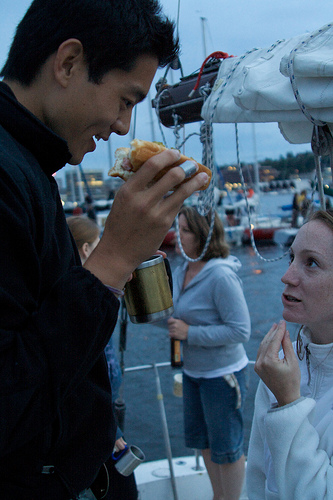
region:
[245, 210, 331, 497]
young girl looking up at young man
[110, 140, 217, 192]
sandwich in young man's right hand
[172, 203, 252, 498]
young lady standing next to the railing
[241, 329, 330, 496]
white jacket young woman is wearing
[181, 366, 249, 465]
blue jean shorts the young woman is wearing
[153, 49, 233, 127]
black and red rooster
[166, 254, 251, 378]
blue jacket woman is wearing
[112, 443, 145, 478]
blue cup person is holding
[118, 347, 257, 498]
white railing next to the young lady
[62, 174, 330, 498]
blue water boats are in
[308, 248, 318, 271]
A woman's right eye.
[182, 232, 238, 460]
A woman in the background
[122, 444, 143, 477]
A silver cup in the background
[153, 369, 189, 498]
A silver pole in the background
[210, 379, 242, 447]
Blue jeans on a woman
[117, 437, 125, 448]
A woman's hand on a cup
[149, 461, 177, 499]
Edge of a white boat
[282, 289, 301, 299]
A woman's lips partially open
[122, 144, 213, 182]
A sandwich being held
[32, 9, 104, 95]
A man's left ear.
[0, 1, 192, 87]
man with black hair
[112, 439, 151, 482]
silver and blue mug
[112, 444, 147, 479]
blue handled mug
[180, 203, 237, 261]
woman with brown hair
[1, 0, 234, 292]
man eating a hotdog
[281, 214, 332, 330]
woman with freckles on face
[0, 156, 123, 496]
man wearing black fleece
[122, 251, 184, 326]
gold and silver mug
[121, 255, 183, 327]
gold and solver coffee mug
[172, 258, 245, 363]
woman wearing gray coat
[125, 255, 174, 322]
coffee in a thermos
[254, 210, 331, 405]
using hand motions to help communicate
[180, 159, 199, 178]
metal ring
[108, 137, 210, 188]
half eaten hot dog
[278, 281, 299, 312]
eating with food in mouth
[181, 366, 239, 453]
short denim jeans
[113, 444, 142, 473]
empty coffee mug with blue handle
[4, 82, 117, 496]
fall jacket with pockets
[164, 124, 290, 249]
boat on dock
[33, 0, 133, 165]
young adult male smiling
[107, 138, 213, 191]
A hotdog in a bun.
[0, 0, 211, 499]
A man holding a hotdog.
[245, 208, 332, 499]
A woman wearing white.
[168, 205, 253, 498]
A woman holding a beer.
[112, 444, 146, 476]
A silver colored cup.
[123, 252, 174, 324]
Gold and silver cup.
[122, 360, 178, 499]
A metal boat rail.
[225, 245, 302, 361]
An area of water.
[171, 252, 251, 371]
A gray colored jacket.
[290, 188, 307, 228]
Two people on a boat.